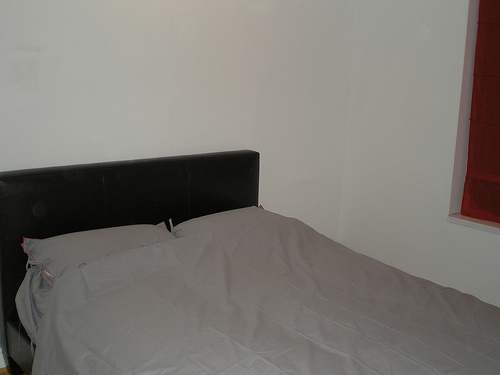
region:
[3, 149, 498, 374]
bed in center of room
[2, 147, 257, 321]
dark rectangular head board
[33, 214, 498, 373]
white linen sheet on bed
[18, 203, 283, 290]
two white pillows on bed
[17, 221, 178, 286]
pillow in white linen pillowcase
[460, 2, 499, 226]
red shade on window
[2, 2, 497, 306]
walls painted white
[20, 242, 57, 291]
pink stitching on side of pillow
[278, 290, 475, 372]
creases in bed sheet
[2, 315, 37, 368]
white mattress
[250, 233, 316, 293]
white fabric on cover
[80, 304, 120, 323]
white fabric on cover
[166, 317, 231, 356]
white fabric on cover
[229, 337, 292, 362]
white fabric on cover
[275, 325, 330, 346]
white fabric on cover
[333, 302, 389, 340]
white fabric on cover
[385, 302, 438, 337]
white fabric on cover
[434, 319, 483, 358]
white fabric on cover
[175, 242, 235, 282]
white fabric on cover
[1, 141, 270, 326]
leather headboard on bed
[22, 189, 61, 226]
large round button on front of headboard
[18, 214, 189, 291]
grey pillow at head of bed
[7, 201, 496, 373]
grey bed sheets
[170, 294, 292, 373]
crease in grey bed sheet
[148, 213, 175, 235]
pointed corner of pillow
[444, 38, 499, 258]
window opening in wall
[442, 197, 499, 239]
ledge of window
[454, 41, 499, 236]
red window covering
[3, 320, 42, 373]
mattress under bedding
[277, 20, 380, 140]
this is the wall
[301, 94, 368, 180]
the wall is white in color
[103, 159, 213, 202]
this is a bed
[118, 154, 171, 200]
the bed is brown in color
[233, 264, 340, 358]
this is a blanket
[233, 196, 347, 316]
the blanket is white in color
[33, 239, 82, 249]
this is a pillow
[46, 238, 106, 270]
the pillow is white in color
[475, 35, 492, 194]
this is the window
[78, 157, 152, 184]
the bed is wooden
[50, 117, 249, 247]
Black head board on the bed.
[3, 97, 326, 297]
Head board on the bed.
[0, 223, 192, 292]
White pillow on the bed.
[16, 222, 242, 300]
Pillow on the bed.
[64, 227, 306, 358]
White blanket on the bed.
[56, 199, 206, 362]
White comforter on the bed.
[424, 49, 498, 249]
Window on the wall.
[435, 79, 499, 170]
Red curtain on the window.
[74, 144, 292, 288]
Black leather headboard.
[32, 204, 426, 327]
Two white pillows on the bed.